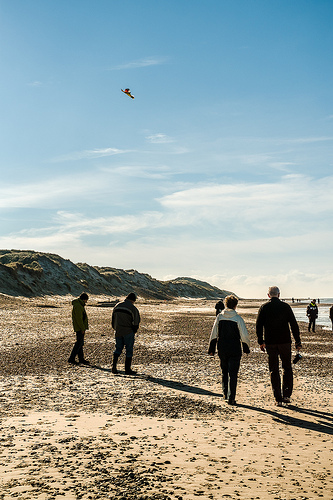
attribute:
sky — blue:
[3, 3, 331, 248]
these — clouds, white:
[4, 128, 329, 255]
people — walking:
[66, 282, 330, 413]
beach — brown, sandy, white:
[1, 312, 331, 499]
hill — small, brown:
[1, 246, 238, 300]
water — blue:
[296, 296, 332, 309]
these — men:
[68, 289, 146, 378]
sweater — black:
[253, 300, 305, 350]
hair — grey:
[261, 285, 284, 299]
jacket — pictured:
[108, 299, 142, 337]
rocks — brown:
[155, 457, 173, 471]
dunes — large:
[1, 249, 68, 299]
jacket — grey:
[67, 297, 93, 334]